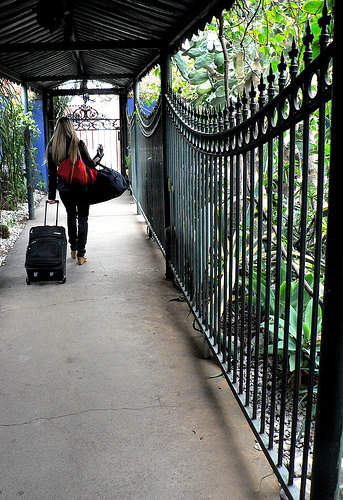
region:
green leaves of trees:
[140, 1, 334, 111]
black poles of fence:
[126, 0, 335, 490]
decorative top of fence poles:
[170, 9, 327, 123]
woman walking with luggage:
[24, 116, 130, 285]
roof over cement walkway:
[0, 0, 225, 93]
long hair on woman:
[45, 115, 74, 159]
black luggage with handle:
[25, 199, 67, 284]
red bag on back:
[56, 155, 95, 187]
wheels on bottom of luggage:
[23, 275, 68, 286]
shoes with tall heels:
[71, 248, 86, 265]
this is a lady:
[43, 125, 101, 223]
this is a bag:
[60, 162, 87, 185]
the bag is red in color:
[62, 168, 80, 180]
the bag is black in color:
[31, 231, 60, 270]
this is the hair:
[51, 131, 73, 160]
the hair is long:
[51, 139, 62, 159]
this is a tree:
[4, 104, 29, 201]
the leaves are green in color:
[10, 108, 31, 151]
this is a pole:
[17, 85, 35, 160]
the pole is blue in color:
[18, 91, 32, 106]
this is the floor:
[48, 329, 114, 394]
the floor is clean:
[85, 429, 129, 459]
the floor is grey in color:
[43, 420, 109, 464]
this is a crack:
[45, 393, 187, 423]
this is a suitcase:
[22, 224, 71, 279]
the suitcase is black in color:
[35, 244, 50, 257]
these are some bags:
[61, 154, 131, 196]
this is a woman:
[46, 109, 104, 266]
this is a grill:
[146, 126, 291, 242]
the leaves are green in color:
[249, 18, 279, 33]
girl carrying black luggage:
[36, 195, 68, 285]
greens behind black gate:
[223, 122, 310, 365]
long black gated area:
[127, 113, 334, 217]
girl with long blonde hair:
[30, 122, 93, 163]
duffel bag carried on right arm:
[87, 152, 129, 207]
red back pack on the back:
[60, 155, 84, 181]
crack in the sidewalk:
[4, 395, 180, 426]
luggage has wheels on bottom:
[22, 270, 63, 284]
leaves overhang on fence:
[181, 49, 223, 96]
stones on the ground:
[9, 215, 24, 232]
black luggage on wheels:
[22, 198, 68, 290]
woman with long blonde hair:
[45, 108, 86, 181]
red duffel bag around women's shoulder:
[59, 140, 98, 190]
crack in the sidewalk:
[9, 385, 224, 438]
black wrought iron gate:
[216, 12, 342, 367]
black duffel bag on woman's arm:
[83, 156, 133, 207]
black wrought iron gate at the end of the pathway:
[53, 97, 126, 189]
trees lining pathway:
[5, 85, 36, 213]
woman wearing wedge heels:
[65, 244, 95, 275]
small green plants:
[256, 261, 326, 378]